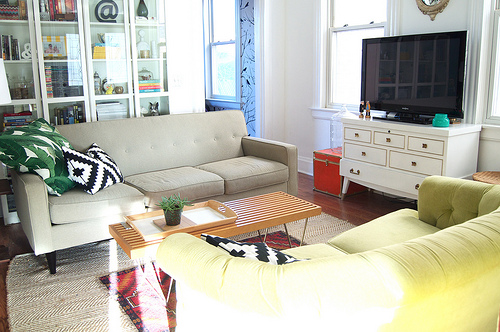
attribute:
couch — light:
[4, 110, 304, 260]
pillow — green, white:
[64, 141, 121, 192]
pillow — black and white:
[62, 142, 125, 194]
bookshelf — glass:
[1, 0, 177, 222]